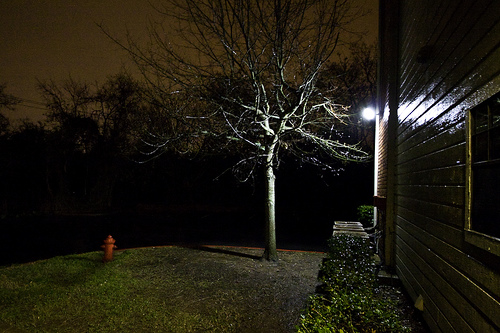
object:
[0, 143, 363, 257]
shadows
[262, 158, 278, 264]
trunk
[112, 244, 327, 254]
line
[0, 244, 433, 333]
ground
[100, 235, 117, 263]
fire hydrant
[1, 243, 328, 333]
grass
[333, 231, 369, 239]
unit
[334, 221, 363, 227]
unit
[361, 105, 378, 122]
light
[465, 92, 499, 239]
window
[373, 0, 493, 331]
side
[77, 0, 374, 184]
tree branches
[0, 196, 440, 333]
yard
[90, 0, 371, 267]
tree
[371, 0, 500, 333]
building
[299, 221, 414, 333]
bushes